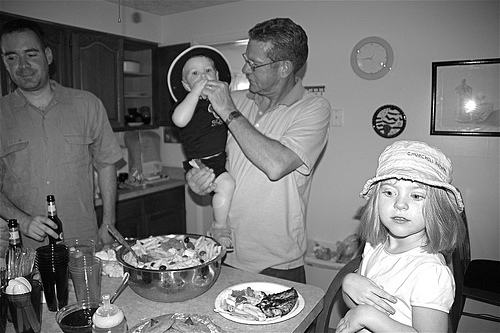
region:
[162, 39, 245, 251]
baby in a hat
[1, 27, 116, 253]
man holding beer bottle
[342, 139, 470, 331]
young blond girl in white hat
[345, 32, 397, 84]
round wall clock with plastic rim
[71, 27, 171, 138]
kitchen cabinet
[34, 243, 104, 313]
stacks of plastic cups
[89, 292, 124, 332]
plastic nipple of baby bottle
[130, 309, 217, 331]
plate of cookies with chocolate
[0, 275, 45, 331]
plastic picnic spoons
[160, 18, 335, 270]
man holding baby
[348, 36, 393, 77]
Clock on the wall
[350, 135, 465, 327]
A girl wearing a bucket hat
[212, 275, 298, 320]
Paper plate filled with food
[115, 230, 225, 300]
Stainless steel salad bowl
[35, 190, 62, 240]
Bottle of beer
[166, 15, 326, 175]
A man feeding a baby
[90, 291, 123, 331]
Baby bottle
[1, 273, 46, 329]
Cup of plastic spoons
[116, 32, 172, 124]
Open kitchen cabinet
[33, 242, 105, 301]
Stacks of plastic cups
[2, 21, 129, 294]
man with short dark hair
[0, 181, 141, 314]
man drinking from a bottle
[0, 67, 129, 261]
man wearing short sleeve shirt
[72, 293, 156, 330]
baby bottle with clear nipple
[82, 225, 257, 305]
silver bowl with fruit salad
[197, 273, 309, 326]
paper plate with food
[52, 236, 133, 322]
stack of plastic cups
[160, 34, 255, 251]
little boy wearing black hat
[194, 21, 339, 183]
man wearing wire rim glasses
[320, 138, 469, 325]
little girl wearing white hat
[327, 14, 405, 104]
a clock on the wall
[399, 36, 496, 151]
a picture frame on the wall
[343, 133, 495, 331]
a young girl wearing a hat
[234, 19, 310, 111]
a man wearing glasses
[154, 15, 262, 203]
a small child wearing a hat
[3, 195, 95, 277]
bottles of beer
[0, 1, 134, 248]
a man holding a bottle of beer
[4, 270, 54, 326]
a cup with plastic spoons in it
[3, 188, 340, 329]
a counter top with food and drinks on it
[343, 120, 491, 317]
a young girl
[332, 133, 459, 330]
young girl wearing a hat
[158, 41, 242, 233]
baby wearing a hat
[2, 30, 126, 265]
man standing next to table holding a beer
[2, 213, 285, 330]
food and drink on table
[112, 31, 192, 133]
cabinet door is open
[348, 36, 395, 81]
round clock on wall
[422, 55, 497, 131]
rectangular picture on wall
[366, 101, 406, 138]
round picture on wall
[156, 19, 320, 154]
man is feeding baby